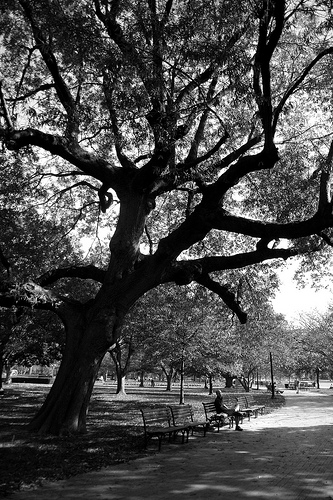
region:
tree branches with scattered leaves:
[15, 8, 171, 170]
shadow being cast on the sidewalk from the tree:
[172, 440, 312, 492]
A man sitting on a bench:
[197, 389, 256, 429]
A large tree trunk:
[33, 363, 97, 445]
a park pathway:
[269, 381, 330, 472]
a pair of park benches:
[137, 402, 207, 442]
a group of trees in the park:
[107, 360, 217, 397]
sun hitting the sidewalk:
[274, 408, 331, 426]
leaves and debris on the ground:
[208, 432, 263, 460]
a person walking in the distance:
[147, 376, 159, 387]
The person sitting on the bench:
[214, 388, 244, 433]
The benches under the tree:
[136, 391, 265, 450]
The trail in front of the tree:
[9, 390, 332, 497]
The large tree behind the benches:
[16, 180, 332, 435]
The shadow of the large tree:
[7, 424, 331, 498]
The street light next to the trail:
[264, 349, 279, 400]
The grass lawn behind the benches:
[1, 375, 289, 499]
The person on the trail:
[291, 373, 304, 397]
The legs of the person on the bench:
[224, 401, 246, 433]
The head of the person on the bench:
[210, 386, 226, 399]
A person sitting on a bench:
[202, 381, 248, 428]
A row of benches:
[130, 397, 276, 434]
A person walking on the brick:
[284, 369, 308, 395]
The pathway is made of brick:
[138, 414, 323, 490]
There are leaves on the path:
[119, 422, 310, 462]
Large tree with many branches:
[19, 38, 284, 427]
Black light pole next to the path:
[260, 345, 277, 402]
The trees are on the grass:
[6, 368, 241, 459]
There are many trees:
[24, 280, 277, 394]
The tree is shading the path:
[37, 366, 313, 495]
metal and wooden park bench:
[137, 404, 191, 454]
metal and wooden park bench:
[163, 400, 207, 441]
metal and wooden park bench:
[200, 396, 248, 434]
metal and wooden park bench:
[231, 394, 265, 418]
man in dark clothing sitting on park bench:
[210, 384, 250, 436]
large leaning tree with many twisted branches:
[0, 0, 332, 440]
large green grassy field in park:
[0, 363, 287, 496]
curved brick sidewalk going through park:
[0, 374, 331, 498]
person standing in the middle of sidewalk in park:
[293, 377, 302, 396]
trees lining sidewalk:
[134, 242, 331, 405]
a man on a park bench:
[214, 387, 243, 429]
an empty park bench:
[168, 399, 208, 436]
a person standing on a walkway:
[293, 376, 300, 393]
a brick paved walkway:
[21, 384, 329, 496]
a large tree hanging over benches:
[3, 2, 330, 431]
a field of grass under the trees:
[1, 383, 275, 486]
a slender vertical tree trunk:
[177, 367, 188, 404]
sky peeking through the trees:
[266, 258, 331, 332]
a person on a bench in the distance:
[269, 383, 283, 395]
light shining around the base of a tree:
[104, 389, 141, 401]